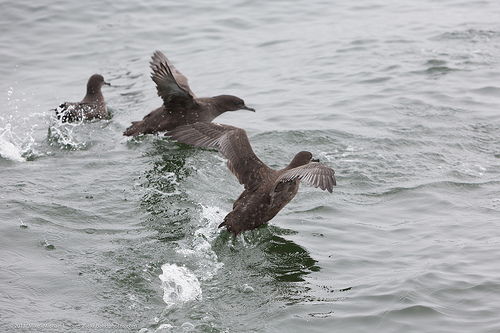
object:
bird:
[164, 127, 337, 238]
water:
[0, 0, 500, 330]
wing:
[271, 162, 338, 193]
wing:
[162, 121, 273, 193]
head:
[289, 150, 320, 164]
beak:
[312, 156, 321, 163]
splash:
[158, 204, 271, 303]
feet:
[232, 230, 262, 251]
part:
[433, 1, 497, 51]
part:
[158, 260, 202, 306]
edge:
[195, 120, 245, 132]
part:
[122, 125, 133, 138]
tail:
[123, 114, 151, 136]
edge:
[230, 191, 246, 210]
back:
[221, 164, 290, 229]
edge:
[274, 232, 317, 261]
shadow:
[215, 222, 322, 287]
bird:
[53, 72, 114, 124]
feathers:
[150, 59, 176, 82]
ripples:
[408, 58, 458, 77]